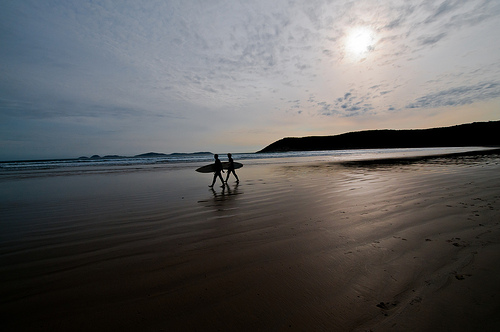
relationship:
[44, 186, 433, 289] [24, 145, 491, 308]
sand on beach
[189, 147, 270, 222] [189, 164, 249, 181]
people holding surfboard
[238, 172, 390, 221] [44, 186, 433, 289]
footprints on sand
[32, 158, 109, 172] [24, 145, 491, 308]
waves in beach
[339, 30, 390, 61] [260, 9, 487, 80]
sun in clouds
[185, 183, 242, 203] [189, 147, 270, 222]
shadow of people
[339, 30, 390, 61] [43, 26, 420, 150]
sun in sky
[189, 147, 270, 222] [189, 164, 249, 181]
people carrying surfboard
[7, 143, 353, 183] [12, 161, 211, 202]
ocean by land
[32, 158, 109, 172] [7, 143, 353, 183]
waves in ocean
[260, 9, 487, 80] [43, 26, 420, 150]
clouds in sky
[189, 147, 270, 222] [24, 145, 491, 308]
people on beach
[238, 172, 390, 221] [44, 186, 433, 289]
footprints in sand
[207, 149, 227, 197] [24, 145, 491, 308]
man on beach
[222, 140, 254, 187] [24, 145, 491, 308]
woman on beach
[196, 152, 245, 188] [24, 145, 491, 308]
people on beach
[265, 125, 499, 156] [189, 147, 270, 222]
hills by people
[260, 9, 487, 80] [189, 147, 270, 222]
clouds above people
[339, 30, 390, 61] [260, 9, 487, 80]
sun behind clouds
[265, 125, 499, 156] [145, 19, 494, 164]
hills in background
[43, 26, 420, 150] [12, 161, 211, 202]
sky above land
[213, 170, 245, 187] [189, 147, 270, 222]
legs on people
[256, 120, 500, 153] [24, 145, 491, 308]
hills near beach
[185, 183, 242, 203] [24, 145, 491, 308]
shadow on beach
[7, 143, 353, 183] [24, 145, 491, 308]
ocean near beach